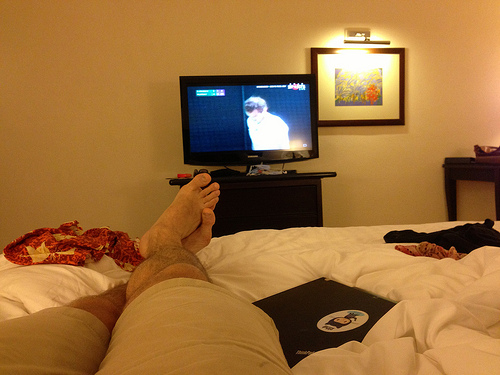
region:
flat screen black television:
[164, 67, 321, 165]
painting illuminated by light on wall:
[302, 16, 418, 138]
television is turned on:
[178, 75, 318, 160]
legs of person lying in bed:
[15, 172, 265, 374]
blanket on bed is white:
[22, 218, 497, 360]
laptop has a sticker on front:
[239, 275, 379, 359]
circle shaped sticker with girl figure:
[319, 303, 366, 334]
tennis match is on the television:
[175, 72, 322, 166]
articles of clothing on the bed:
[374, 207, 496, 262]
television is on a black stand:
[166, 71, 336, 224]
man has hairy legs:
[4, 176, 262, 372]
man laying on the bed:
[2, 236, 498, 372]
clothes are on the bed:
[3, 227, 135, 265]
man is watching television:
[178, 72, 328, 226]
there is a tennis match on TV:
[183, 77, 313, 152]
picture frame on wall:
[311, 27, 401, 129]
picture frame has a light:
[312, 27, 408, 123]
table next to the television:
[446, 147, 498, 217]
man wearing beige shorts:
[2, 287, 286, 371]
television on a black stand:
[173, 172, 330, 228]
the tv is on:
[175, 53, 364, 176]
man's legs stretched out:
[2, 120, 332, 372]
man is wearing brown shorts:
[0, 234, 311, 369]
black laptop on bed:
[220, 247, 422, 359]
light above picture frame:
[315, 11, 397, 59]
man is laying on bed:
[0, 146, 491, 360]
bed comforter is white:
[7, 214, 486, 373]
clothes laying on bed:
[356, 187, 480, 274]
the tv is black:
[155, 59, 365, 185]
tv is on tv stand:
[136, 59, 390, 239]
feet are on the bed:
[115, 165, 228, 259]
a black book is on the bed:
[258, 262, 395, 354]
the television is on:
[143, 41, 330, 176]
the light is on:
[297, 17, 408, 73]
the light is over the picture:
[288, 15, 404, 130]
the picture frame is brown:
[302, 39, 418, 144]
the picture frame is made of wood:
[296, 45, 412, 122]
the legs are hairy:
[72, 203, 231, 332]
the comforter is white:
[12, 223, 479, 358]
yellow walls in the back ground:
[35, 74, 140, 156]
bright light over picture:
[315, 21, 417, 55]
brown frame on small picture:
[380, 40, 420, 115]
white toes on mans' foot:
[170, 165, 237, 207]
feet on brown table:
[425, 147, 467, 199]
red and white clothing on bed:
[16, 210, 126, 260]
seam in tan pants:
[115, 268, 276, 330]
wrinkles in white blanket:
[387, 297, 448, 357]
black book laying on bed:
[253, 262, 414, 356]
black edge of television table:
[295, 163, 349, 184]